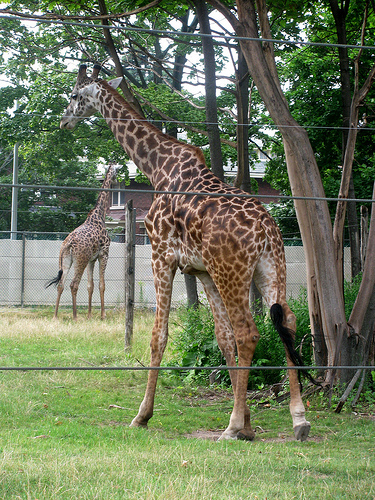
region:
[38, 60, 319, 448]
Animals in a pen.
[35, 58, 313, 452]
Two giraffes fenced in a pen.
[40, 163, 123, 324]
One giraffe looking out over a fence.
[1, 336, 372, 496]
Green and brown grass of a fenced in pen.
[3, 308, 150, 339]
Brown grass of a giraffe's pen.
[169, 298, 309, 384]
Small green bushes behind a tree.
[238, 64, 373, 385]
Large tree beside a giraffe.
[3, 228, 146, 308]
Metal chain fence in a giraffe pen.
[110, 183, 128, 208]
Window of a house.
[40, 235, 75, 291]
Tail of a giraffe.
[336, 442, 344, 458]
part of a field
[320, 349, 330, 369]
part of a stem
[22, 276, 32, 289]
part of a fence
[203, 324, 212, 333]
part of a bush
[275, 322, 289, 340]
part of a tail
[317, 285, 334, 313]
edge of a stem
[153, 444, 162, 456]
part of a grass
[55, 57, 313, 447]
a giraffe facing away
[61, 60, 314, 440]
a giraffe walking in the grass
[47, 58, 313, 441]
a giraffe in an enclosure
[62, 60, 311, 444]
a giraffe behind a fence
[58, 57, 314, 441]
a giraffe near trees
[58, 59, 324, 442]
An animal with brown spots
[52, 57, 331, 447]
A giraffe standing in the grass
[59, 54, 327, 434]
A tall mammal behind a fence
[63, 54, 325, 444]
a spotted animal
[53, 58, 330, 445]
a spotted mammal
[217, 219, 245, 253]
Dark spots on an animal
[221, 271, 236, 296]
Dark spots on an animal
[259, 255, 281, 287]
Dark spots on an animal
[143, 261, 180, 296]
Dark spots on an animal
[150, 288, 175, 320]
Dark spots on an animal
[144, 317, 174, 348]
Dark spots on an animal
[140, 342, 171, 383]
Dark spots on an animal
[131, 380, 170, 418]
Dark spots on an animal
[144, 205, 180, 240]
Dark spots on an animal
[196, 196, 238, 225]
Dark spots on an animal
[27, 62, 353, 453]
giraffes in an enclosure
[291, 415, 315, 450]
back hoof of a giraffe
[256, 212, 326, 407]
tail of a giraffe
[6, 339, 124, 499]
green grass by giraffes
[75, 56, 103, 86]
horns on a giraffe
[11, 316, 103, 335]
brown grass by giraffe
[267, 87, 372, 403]
trunk of a tree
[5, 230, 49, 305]
fence behind the giraffes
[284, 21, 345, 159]
green leaves on a tree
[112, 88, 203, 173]
mane on a giraffe